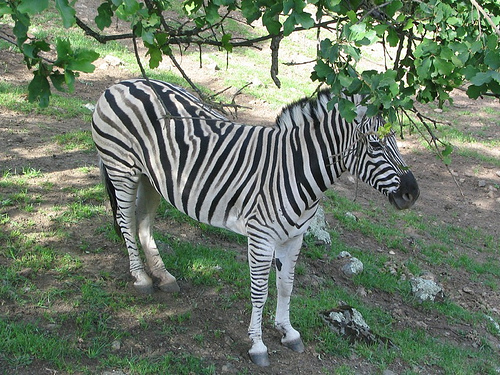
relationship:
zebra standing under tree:
[91, 67, 420, 364] [235, 9, 324, 71]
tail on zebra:
[100, 159, 124, 241] [91, 67, 420, 364]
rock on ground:
[411, 270, 448, 305] [0, 0, 500, 374]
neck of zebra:
[289, 115, 345, 208] [91, 67, 420, 364]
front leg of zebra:
[273, 232, 310, 354] [91, 67, 420, 364]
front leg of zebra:
[245, 232, 273, 369] [91, 67, 420, 364]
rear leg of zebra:
[136, 176, 181, 295] [91, 67, 420, 364]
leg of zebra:
[100, 167, 151, 296] [91, 67, 420, 364]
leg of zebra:
[242, 223, 274, 370] [91, 67, 420, 364]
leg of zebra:
[268, 236, 307, 356] [91, 67, 420, 364]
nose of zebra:
[383, 170, 428, 215] [88, 87, 420, 339]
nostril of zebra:
[380, 177, 424, 212] [91, 67, 420, 364]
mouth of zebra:
[391, 193, 406, 212] [91, 67, 420, 364]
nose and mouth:
[383, 186, 424, 218] [387, 172, 420, 215]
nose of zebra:
[383, 186, 424, 218] [91, 67, 420, 364]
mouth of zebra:
[387, 172, 420, 215] [91, 67, 420, 364]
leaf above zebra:
[337, 97, 357, 121] [91, 67, 420, 364]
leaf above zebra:
[342, 22, 363, 42] [91, 67, 420, 364]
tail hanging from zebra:
[100, 159, 124, 241] [91, 67, 420, 364]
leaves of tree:
[1, 1, 498, 161] [4, 0, 498, 187]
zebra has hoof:
[91, 67, 420, 364] [158, 269, 181, 293]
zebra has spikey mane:
[91, 67, 420, 364] [254, 77, 329, 143]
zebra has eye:
[91, 67, 420, 364] [365, 132, 391, 158]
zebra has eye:
[91, 67, 420, 364] [370, 136, 387, 152]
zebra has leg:
[91, 67, 420, 364] [243, 228, 278, 369]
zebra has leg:
[91, 67, 420, 364] [93, 130, 151, 287]